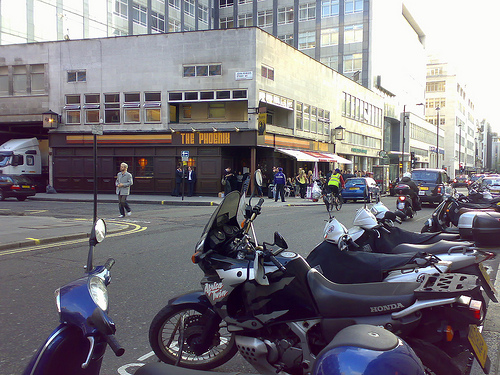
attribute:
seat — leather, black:
[307, 266, 418, 316]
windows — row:
[65, 94, 162, 126]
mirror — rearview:
[253, 167, 267, 189]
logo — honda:
[369, 299, 406, 321]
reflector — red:
[469, 300, 487, 321]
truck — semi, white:
[1, 138, 49, 193]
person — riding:
[326, 170, 346, 194]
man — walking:
[114, 162, 135, 220]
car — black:
[410, 168, 458, 201]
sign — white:
[90, 121, 108, 136]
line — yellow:
[71, 216, 148, 237]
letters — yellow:
[176, 130, 234, 146]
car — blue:
[339, 176, 384, 204]